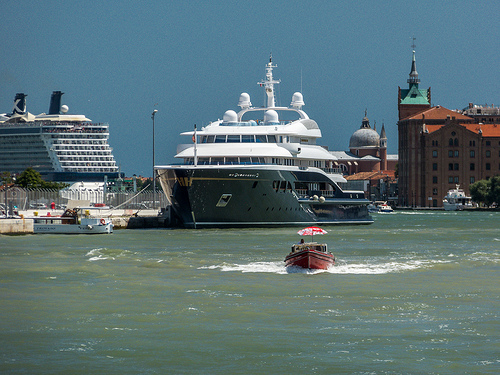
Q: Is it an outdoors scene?
A: Yes, it is outdoors.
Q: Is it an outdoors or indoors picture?
A: It is outdoors.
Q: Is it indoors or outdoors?
A: It is outdoors.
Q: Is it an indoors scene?
A: No, it is outdoors.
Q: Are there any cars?
A: No, there are no cars.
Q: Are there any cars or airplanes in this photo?
A: No, there are no cars or airplanes.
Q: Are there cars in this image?
A: No, there are no cars.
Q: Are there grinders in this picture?
A: No, there are no grinders.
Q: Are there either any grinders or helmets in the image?
A: No, there are no grinders or helmets.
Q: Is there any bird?
A: No, there are no birds.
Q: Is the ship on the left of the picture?
A: Yes, the ship is on the left of the image.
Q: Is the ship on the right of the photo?
A: No, the ship is on the left of the image.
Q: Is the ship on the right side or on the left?
A: The ship is on the left of the image.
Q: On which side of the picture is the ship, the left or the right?
A: The ship is on the left of the image.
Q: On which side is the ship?
A: The ship is on the left of the image.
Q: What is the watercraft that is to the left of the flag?
A: The watercraft is a ship.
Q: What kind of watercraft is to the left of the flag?
A: The watercraft is a ship.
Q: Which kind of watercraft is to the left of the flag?
A: The watercraft is a ship.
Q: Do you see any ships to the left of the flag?
A: Yes, there is a ship to the left of the flag.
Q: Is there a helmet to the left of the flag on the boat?
A: No, there is a ship to the left of the flag.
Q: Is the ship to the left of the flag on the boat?
A: Yes, the ship is to the left of the flag.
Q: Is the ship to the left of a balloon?
A: No, the ship is to the left of the flag.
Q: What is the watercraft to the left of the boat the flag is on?
A: The watercraft is a ship.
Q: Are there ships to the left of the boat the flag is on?
A: Yes, there is a ship to the left of the boat.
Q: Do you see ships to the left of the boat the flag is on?
A: Yes, there is a ship to the left of the boat.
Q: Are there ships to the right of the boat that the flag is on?
A: No, the ship is to the left of the boat.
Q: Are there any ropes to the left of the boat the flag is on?
A: No, there is a ship to the left of the boat.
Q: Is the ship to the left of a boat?
A: Yes, the ship is to the left of a boat.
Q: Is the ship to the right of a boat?
A: No, the ship is to the left of a boat.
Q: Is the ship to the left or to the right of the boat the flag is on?
A: The ship is to the left of the boat.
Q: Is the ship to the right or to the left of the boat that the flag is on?
A: The ship is to the left of the boat.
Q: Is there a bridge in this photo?
A: Yes, there is a bridge.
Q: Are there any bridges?
A: Yes, there is a bridge.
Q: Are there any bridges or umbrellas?
A: Yes, there is a bridge.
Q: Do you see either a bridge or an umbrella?
A: Yes, there is a bridge.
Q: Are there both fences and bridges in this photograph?
A: Yes, there are both a bridge and a fence.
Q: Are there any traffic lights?
A: No, there are no traffic lights.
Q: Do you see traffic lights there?
A: No, there are no traffic lights.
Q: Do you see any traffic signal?
A: No, there are no traffic lights.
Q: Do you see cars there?
A: No, there are no cars.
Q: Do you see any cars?
A: No, there are no cars.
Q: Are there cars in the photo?
A: No, there are no cars.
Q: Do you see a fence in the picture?
A: Yes, there is a fence.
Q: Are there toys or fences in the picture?
A: Yes, there is a fence.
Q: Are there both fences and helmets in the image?
A: No, there is a fence but no helmets.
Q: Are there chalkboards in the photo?
A: No, there are no chalkboards.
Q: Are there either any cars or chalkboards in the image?
A: No, there are no chalkboards or cars.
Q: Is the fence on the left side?
A: Yes, the fence is on the left of the image.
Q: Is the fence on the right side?
A: No, the fence is on the left of the image.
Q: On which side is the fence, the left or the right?
A: The fence is on the left of the image.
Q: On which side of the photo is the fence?
A: The fence is on the left of the image.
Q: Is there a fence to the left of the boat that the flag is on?
A: Yes, there is a fence to the left of the boat.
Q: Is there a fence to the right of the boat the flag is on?
A: No, the fence is to the left of the boat.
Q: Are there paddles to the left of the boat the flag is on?
A: No, there is a fence to the left of the boat.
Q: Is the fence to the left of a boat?
A: Yes, the fence is to the left of a boat.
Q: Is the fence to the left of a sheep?
A: No, the fence is to the left of a boat.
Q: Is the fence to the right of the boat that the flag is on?
A: No, the fence is to the left of the boat.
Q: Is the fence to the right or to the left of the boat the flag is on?
A: The fence is to the left of the boat.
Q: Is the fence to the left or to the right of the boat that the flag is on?
A: The fence is to the left of the boat.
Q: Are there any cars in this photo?
A: No, there are no cars.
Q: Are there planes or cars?
A: No, there are no cars or planes.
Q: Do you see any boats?
A: Yes, there is a boat.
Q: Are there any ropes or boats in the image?
A: Yes, there is a boat.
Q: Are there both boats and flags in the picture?
A: Yes, there are both a boat and a flag.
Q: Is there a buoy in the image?
A: No, there are no buoys.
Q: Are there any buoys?
A: No, there are no buoys.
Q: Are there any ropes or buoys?
A: No, there are no buoys or ropes.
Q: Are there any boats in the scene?
A: Yes, there is a boat.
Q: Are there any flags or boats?
A: Yes, there is a boat.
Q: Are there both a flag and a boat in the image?
A: Yes, there are both a boat and a flag.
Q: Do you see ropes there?
A: No, there are no ropes.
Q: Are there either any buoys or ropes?
A: No, there are no ropes or buoys.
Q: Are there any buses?
A: No, there are no buses.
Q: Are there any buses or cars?
A: No, there are no buses or cars.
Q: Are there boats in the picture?
A: Yes, there is a boat.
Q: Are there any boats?
A: Yes, there is a boat.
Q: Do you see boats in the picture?
A: Yes, there is a boat.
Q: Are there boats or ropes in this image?
A: Yes, there is a boat.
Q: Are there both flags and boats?
A: Yes, there are both a boat and a flag.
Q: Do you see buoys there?
A: No, there are no buoys.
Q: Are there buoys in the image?
A: No, there are no buoys.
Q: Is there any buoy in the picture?
A: No, there are no buoys.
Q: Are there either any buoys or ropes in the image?
A: No, there are no buoys or ropes.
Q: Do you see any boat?
A: Yes, there is a boat.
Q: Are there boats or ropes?
A: Yes, there is a boat.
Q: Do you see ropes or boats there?
A: Yes, there is a boat.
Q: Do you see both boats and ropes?
A: No, there is a boat but no ropes.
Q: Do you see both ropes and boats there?
A: No, there is a boat but no ropes.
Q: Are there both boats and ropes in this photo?
A: No, there is a boat but no ropes.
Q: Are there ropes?
A: No, there are no ropes.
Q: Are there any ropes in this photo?
A: No, there are no ropes.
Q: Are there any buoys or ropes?
A: No, there are no ropes or buoys.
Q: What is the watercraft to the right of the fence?
A: The watercraft is a boat.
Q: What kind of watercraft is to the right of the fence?
A: The watercraft is a boat.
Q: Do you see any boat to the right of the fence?
A: Yes, there is a boat to the right of the fence.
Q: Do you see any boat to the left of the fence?
A: No, the boat is to the right of the fence.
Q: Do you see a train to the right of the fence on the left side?
A: No, there is a boat to the right of the fence.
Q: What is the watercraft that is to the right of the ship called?
A: The watercraft is a boat.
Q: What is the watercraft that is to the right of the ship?
A: The watercraft is a boat.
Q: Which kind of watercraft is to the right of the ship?
A: The watercraft is a boat.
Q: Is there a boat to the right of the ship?
A: Yes, there is a boat to the right of the ship.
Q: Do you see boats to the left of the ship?
A: No, the boat is to the right of the ship.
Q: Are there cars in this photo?
A: No, there are no cars.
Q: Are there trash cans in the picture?
A: No, there are no trash cans.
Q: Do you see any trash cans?
A: No, there are no trash cans.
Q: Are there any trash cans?
A: No, there are no trash cans.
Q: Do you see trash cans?
A: No, there are no trash cans.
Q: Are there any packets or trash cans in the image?
A: No, there are no trash cans or packets.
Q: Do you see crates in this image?
A: No, there are no crates.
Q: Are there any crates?
A: No, there are no crates.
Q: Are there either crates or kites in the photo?
A: No, there are no crates or kites.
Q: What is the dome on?
A: The dome is on the building.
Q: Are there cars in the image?
A: No, there are no cars.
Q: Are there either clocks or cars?
A: No, there are no cars or clocks.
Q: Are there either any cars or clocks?
A: No, there are no cars or clocks.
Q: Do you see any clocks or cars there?
A: No, there are no cars or clocks.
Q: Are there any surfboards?
A: No, there are no surfboards.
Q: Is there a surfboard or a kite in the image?
A: No, there are no surfboards or kites.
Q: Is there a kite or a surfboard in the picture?
A: No, there are no surfboards or kites.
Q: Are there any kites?
A: No, there are no kites.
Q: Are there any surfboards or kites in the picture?
A: No, there are no kites or surfboards.